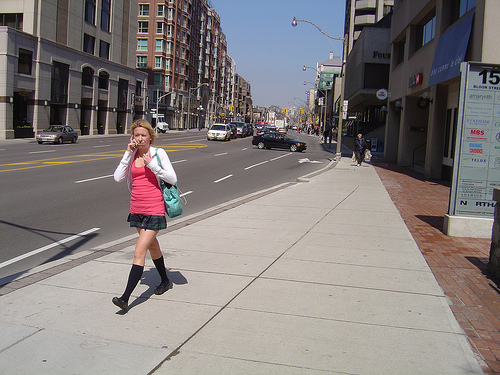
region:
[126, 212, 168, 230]
Green and blue plaid mini skirt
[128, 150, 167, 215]
Long fit pink shirt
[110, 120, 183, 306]
Girl carrying a turquoise purse walking down the side walk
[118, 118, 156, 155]
Girl talking on a cell phone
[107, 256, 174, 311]
Knee high black socks with black flat dress shoes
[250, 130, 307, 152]
Black four door car making a turn on a road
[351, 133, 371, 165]
A person in black jacket carrying shopping bags in both hands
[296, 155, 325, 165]
White traffic arrows painted on the road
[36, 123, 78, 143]
metallic tan vehicle driving down the road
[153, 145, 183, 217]
Large turquoise over the shoulder bag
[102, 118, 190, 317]
A woman talking on a cellphone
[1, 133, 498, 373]
A sidewalk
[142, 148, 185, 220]
A teal colored shoulder bag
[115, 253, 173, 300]
Long black socks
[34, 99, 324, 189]
Vehicles on the road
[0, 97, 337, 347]
A road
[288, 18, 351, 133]
Streetlights along the road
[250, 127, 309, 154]
A black car turning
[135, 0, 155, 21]
The window is rectangle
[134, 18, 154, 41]
The window is rectangle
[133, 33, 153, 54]
The window is rectangle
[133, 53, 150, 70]
The window is rectangle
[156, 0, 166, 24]
The window is rectangle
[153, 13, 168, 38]
The window is rectangle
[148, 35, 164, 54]
The window is rectangle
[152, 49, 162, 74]
The window is rectangle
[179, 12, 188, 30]
The window is rectangle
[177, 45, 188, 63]
The window is rectangle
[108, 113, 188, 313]
A woman in a black miniskirt walking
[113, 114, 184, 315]
A woman walking while on her cellphone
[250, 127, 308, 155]
A black four door sedan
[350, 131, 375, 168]
A person walking while carrying shopping bags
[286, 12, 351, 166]
A street lamp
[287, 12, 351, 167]
A street light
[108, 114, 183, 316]
A woman taking a brisk walk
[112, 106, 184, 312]
A woman walking in action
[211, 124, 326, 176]
A black sedan making a left turn from the street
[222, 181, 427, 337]
A portion of double wide sidewalk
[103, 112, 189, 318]
A young girl walking in the street on her cell phone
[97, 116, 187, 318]
A young girl walking in the street on her cell phone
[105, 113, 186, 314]
A young girl walking in the street on her cell phone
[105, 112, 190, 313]
A young girl walking in the street on her cell phone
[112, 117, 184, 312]
blonde woman walking on a gray sidewalk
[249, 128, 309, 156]
black car sideways on the dark gray street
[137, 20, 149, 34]
A window on the side of a building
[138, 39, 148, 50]
A window on the side of a building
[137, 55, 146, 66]
A window on the side of a building